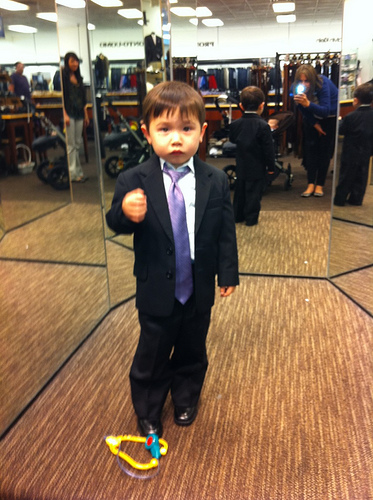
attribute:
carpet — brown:
[2, 196, 372, 498]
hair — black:
[139, 75, 239, 116]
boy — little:
[104, 80, 238, 438]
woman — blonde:
[286, 62, 368, 176]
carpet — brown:
[0, 277, 372, 499]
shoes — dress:
[132, 403, 216, 440]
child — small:
[109, 82, 238, 442]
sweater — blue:
[297, 76, 340, 128]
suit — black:
[111, 152, 234, 439]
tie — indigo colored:
[158, 158, 203, 307]